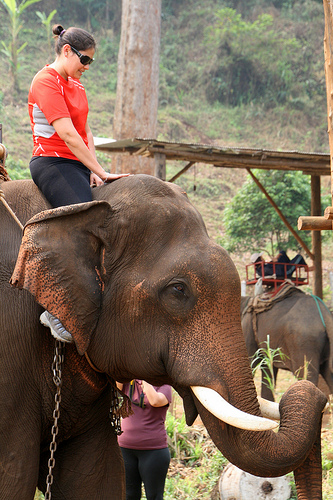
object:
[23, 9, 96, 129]
top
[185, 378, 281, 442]
tusk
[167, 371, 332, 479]
trunk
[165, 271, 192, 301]
eye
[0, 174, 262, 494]
elephant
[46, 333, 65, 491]
chain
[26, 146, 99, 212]
trouser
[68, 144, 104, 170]
hand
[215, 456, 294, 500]
stone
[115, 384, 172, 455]
top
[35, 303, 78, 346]
shoe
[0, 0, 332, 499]
picture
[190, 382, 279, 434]
tusks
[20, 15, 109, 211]
woman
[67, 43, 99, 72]
sun glasses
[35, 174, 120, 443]
elephant's neck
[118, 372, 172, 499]
woman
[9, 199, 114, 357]
brown ear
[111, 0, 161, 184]
stem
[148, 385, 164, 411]
elbow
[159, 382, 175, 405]
sleeve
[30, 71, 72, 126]
sleeve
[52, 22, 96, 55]
hair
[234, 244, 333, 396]
elephant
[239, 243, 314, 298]
saddle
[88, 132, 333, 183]
platform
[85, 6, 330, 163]
terrain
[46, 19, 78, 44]
bun